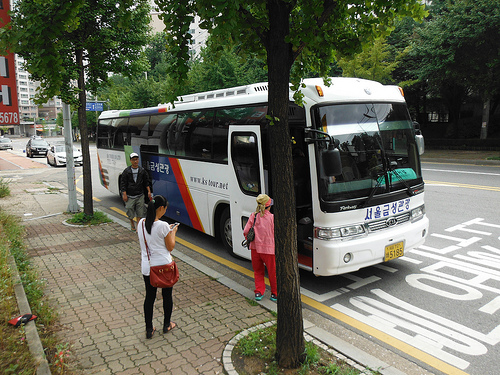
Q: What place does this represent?
A: It represents the street.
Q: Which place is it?
A: It is a street.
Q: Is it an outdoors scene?
A: Yes, it is outdoors.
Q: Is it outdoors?
A: Yes, it is outdoors.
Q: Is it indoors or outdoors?
A: It is outdoors.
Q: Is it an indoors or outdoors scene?
A: It is outdoors.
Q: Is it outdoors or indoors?
A: It is outdoors.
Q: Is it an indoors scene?
A: No, it is outdoors.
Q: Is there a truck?
A: No, there are no trucks.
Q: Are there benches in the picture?
A: No, there are no benches.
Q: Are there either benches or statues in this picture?
A: No, there are no benches or statues.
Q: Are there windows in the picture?
A: Yes, there is a window.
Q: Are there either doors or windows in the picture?
A: Yes, there is a window.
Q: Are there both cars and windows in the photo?
A: Yes, there are both a window and a car.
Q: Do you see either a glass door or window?
A: Yes, there is a glass window.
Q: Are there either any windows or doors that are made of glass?
A: Yes, the window is made of glass.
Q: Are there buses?
A: Yes, there is a bus.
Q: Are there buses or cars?
A: Yes, there is a bus.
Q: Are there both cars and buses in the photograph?
A: Yes, there are both a bus and a car.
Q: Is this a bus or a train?
A: This is a bus.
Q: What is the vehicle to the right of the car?
A: The vehicle is a bus.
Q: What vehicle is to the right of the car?
A: The vehicle is a bus.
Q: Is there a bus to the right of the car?
A: Yes, there is a bus to the right of the car.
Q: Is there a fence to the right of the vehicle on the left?
A: No, there is a bus to the right of the car.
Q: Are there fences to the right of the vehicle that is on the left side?
A: No, there is a bus to the right of the car.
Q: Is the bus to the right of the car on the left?
A: Yes, the bus is to the right of the car.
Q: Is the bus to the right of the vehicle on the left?
A: Yes, the bus is to the right of the car.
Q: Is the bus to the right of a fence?
A: No, the bus is to the right of the car.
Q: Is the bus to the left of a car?
A: No, the bus is to the right of a car.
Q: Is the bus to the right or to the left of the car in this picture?
A: The bus is to the right of the car.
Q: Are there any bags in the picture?
A: Yes, there is a bag.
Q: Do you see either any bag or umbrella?
A: Yes, there is a bag.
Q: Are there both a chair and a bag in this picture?
A: No, there is a bag but no chairs.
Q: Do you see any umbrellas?
A: No, there are no umbrellas.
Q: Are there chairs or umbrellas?
A: No, there are no umbrellas or chairs.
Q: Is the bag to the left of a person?
A: Yes, the bag is to the left of a person.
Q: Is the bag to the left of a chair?
A: No, the bag is to the left of a person.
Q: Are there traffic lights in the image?
A: No, there are no traffic lights.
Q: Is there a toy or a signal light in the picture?
A: No, there are no traffic lights or toys.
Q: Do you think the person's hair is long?
A: Yes, the hair is long.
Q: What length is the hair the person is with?
A: The hair is long.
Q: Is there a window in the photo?
A: Yes, there is a window.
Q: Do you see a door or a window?
A: Yes, there is a window.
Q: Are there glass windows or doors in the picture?
A: Yes, there is a glass window.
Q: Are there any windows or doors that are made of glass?
A: Yes, the window is made of glass.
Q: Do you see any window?
A: Yes, there is a window.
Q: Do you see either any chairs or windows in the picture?
A: Yes, there is a window.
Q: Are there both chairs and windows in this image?
A: No, there is a window but no chairs.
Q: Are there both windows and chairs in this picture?
A: No, there is a window but no chairs.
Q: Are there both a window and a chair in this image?
A: No, there is a window but no chairs.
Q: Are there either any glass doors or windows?
A: Yes, there is a glass window.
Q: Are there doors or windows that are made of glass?
A: Yes, the window is made of glass.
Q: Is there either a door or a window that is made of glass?
A: Yes, the window is made of glass.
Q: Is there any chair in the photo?
A: No, there are no chairs.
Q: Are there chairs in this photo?
A: No, there are no chairs.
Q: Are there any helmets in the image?
A: No, there are no helmets.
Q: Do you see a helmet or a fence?
A: No, there are no helmets or fences.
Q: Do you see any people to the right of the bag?
A: Yes, there is a person to the right of the bag.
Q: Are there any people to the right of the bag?
A: Yes, there is a person to the right of the bag.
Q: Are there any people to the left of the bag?
A: No, the person is to the right of the bag.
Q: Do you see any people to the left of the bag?
A: No, the person is to the right of the bag.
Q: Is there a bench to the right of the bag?
A: No, there is a person to the right of the bag.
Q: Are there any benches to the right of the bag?
A: No, there is a person to the right of the bag.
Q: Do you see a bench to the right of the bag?
A: No, there is a person to the right of the bag.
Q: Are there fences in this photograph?
A: No, there are no fences.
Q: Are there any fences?
A: No, there are no fences.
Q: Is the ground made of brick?
A: Yes, the ground is made of brick.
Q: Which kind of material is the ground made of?
A: The ground is made of brick.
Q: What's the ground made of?
A: The ground is made of brick.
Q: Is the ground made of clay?
A: No, the ground is made of brick.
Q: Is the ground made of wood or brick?
A: The ground is made of brick.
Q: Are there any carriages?
A: No, there are no carriages.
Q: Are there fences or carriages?
A: No, there are no carriages or fences.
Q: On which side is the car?
A: The car is on the left of the image.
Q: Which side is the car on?
A: The car is on the left of the image.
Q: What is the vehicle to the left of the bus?
A: The vehicle is a car.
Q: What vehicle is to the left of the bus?
A: The vehicle is a car.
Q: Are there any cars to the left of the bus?
A: Yes, there is a car to the left of the bus.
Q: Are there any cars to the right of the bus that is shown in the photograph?
A: No, the car is to the left of the bus.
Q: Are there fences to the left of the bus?
A: No, there is a car to the left of the bus.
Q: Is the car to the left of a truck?
A: No, the car is to the left of the bus.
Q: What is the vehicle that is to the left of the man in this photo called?
A: The vehicle is a car.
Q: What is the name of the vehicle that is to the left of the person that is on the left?
A: The vehicle is a car.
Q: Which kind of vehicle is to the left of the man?
A: The vehicle is a car.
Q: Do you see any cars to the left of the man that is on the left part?
A: Yes, there is a car to the left of the man.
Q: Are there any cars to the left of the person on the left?
A: Yes, there is a car to the left of the man.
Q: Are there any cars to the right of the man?
A: No, the car is to the left of the man.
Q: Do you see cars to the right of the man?
A: No, the car is to the left of the man.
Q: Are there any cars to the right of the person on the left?
A: No, the car is to the left of the man.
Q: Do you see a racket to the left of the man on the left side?
A: No, there is a car to the left of the man.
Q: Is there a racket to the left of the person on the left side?
A: No, there is a car to the left of the man.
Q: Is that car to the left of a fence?
A: No, the car is to the left of the man.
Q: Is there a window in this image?
A: Yes, there is a window.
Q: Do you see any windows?
A: Yes, there is a window.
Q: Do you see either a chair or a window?
A: Yes, there is a window.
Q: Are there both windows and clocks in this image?
A: No, there is a window but no clocks.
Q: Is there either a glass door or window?
A: Yes, there is a glass window.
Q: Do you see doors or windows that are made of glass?
A: Yes, the window is made of glass.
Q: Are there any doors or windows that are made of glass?
A: Yes, the window is made of glass.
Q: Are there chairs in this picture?
A: No, there are no chairs.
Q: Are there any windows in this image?
A: Yes, there is a window.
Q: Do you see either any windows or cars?
A: Yes, there is a window.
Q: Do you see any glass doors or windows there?
A: Yes, there is a glass window.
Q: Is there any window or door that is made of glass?
A: Yes, the window is made of glass.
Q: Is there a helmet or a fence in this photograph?
A: No, there are no fences or helmets.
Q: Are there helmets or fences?
A: No, there are no fences or helmets.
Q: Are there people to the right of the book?
A: Yes, there is a person to the right of the book.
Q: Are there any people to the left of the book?
A: No, the person is to the right of the book.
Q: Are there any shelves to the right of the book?
A: No, there is a person to the right of the book.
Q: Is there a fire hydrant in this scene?
A: No, there are no fire hydrants.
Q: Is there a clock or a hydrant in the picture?
A: No, there are no fire hydrants or clocks.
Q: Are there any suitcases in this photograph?
A: No, there are no suitcases.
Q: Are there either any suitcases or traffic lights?
A: No, there are no suitcases or traffic lights.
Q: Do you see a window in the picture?
A: Yes, there is a window.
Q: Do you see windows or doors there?
A: Yes, there is a window.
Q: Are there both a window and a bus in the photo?
A: Yes, there are both a window and a bus.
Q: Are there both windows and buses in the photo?
A: Yes, there are both a window and a bus.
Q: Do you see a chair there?
A: No, there are no chairs.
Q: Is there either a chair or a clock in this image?
A: No, there are no chairs or clocks.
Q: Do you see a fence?
A: No, there are no fences.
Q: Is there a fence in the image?
A: No, there are no fences.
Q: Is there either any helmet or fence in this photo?
A: No, there are no fences or helmets.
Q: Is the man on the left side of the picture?
A: Yes, the man is on the left of the image.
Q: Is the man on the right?
A: No, the man is on the left of the image.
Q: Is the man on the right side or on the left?
A: The man is on the left of the image.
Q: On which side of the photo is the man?
A: The man is on the left of the image.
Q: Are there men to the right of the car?
A: Yes, there is a man to the right of the car.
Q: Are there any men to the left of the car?
A: No, the man is to the right of the car.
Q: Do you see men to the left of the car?
A: No, the man is to the right of the car.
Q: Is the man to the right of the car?
A: Yes, the man is to the right of the car.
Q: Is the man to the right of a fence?
A: No, the man is to the right of the car.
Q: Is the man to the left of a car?
A: No, the man is to the right of a car.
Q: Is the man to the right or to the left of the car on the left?
A: The man is to the right of the car.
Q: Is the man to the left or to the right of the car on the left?
A: The man is to the right of the car.